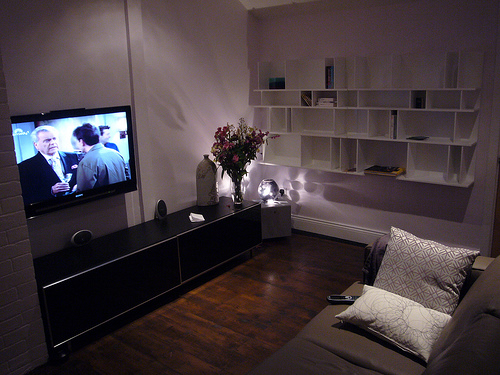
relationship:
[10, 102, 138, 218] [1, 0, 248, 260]
television mounted on wall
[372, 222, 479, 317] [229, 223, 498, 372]
pillow on top of couch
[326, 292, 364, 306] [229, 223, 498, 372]
remote on top of couch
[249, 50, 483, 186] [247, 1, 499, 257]
shelves mounted on wall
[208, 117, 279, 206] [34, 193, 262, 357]
flowers on top of stand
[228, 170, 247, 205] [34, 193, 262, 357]
vase on top of stand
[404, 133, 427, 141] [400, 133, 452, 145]
book on top of shelf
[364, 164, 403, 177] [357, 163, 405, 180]
book on top of shelf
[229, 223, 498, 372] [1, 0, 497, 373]
couch inside of living room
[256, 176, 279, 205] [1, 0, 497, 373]
vase in corner of living room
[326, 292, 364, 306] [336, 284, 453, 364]
remote next to pillow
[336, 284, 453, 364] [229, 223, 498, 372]
pillow on top of couch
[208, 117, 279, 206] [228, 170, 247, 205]
flowers inside of vase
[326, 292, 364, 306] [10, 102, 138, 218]
remote for television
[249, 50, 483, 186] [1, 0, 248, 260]
shelves mounted on wall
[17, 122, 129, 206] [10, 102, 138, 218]
men shown on television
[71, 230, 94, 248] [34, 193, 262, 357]
speaker on top of stand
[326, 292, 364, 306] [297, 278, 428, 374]
remote on top of cushion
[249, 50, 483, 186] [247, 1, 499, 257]
shelves attached to wall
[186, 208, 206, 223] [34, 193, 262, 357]
book on top of stand